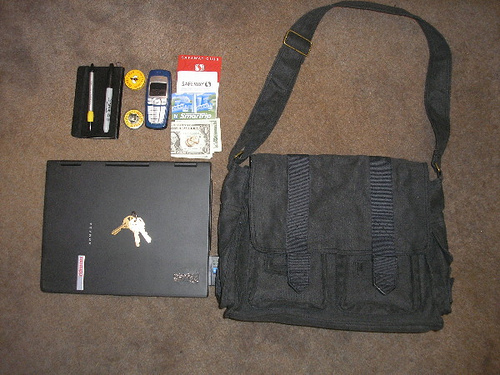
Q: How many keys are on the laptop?
A: Three.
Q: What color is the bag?
A: Black.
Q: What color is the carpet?
A: Brown.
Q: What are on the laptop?
A: Keys.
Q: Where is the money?
A: Above the laptop.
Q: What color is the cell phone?
A: Blue, silver, and black.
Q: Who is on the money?
A: George Washington.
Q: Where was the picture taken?
A: On the carpet.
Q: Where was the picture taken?
A: The bedroom.